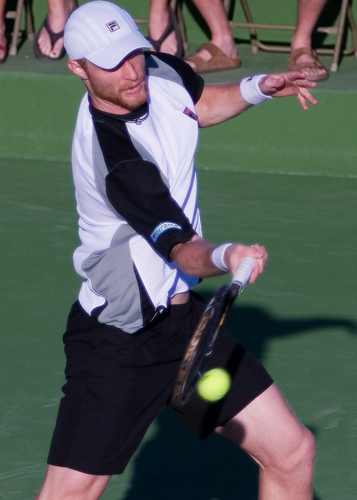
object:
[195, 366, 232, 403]
ball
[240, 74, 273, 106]
band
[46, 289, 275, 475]
shorts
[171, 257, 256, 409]
racket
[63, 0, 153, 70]
hat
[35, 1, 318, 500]
adult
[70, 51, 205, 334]
shirt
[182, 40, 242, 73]
shoes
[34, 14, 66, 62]
shoes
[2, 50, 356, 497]
court